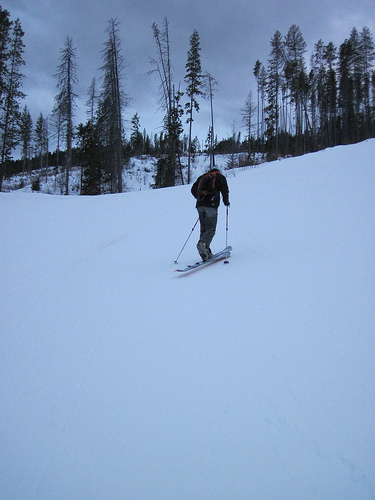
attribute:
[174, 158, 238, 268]
skier — skiing, looking down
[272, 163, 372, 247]
snow — white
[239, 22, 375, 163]
trees — tall, thin, green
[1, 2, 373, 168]
sky — dull, cloudy, gray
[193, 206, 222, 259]
pants — blue, gray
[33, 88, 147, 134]
cloud — white, dark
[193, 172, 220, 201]
backpack — orange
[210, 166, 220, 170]
helmet — white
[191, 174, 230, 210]
jacket — black